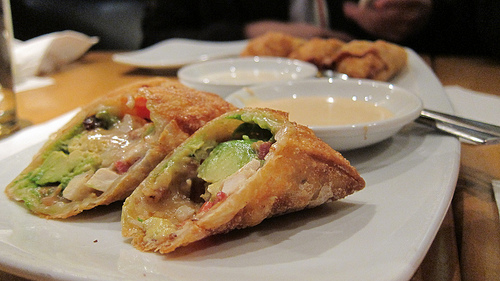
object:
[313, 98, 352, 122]
sauce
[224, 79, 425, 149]
bowl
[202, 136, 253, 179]
avacado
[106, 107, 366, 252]
shell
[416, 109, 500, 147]
handle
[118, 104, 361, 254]
food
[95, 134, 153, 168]
chicken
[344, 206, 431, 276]
plate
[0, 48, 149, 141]
table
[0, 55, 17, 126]
water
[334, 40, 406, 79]
bread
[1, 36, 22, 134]
glass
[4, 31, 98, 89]
napkin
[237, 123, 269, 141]
olive